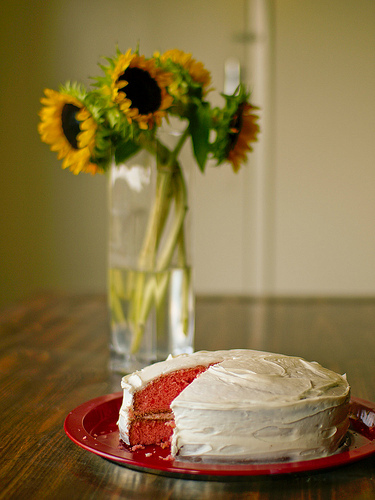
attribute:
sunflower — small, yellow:
[36, 79, 109, 177]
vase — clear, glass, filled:
[106, 130, 201, 375]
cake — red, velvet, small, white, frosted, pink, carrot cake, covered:
[118, 349, 352, 464]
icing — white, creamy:
[118, 349, 351, 462]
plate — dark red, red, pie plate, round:
[63, 392, 374, 479]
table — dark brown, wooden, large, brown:
[2, 290, 374, 500]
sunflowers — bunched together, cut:
[34, 46, 260, 358]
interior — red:
[131, 362, 220, 458]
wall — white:
[0, 0, 373, 299]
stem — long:
[123, 130, 196, 355]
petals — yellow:
[34, 86, 96, 175]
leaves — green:
[64, 83, 137, 171]